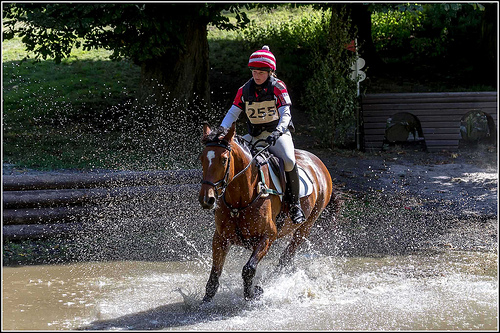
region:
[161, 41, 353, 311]
woman riding horse in competition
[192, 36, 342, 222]
rider wearing vest with three-digit number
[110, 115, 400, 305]
horse splashing through water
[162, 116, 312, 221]
rider holding onto reins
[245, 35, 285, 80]
rider wearing knitted red and white hat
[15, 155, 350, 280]
wooden barrier behind horse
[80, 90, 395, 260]
drops of water surrounding horse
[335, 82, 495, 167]
arched cutouts in wall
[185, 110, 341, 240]
rider wearing long black boots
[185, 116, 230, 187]
white splotch with tail between eyes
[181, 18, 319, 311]
Girl riding a horse.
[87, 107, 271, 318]
Horse in the water.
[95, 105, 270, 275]
Rider riding horse through the water.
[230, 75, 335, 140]
Rider with 255 on the jersey.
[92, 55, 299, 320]
Water spray from the horse running.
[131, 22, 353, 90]
Trees behind the horse rider.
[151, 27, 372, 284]
Girl riding in the water.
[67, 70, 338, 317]
Water polo.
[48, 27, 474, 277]
The horse is running through the water.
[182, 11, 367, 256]
Girl riding a horse with a jersey.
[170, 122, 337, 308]
A BROWN HORSE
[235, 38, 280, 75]
A RED AND WHITE HAT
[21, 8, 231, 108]
A TREE IN THE BACKGROUND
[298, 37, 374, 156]
TALL WEEDS BY THE FLAG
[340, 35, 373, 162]
A RED FLAG ON A POLE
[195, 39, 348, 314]
A PERSON RIDING A HORSE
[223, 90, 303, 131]
THE NUMBER 225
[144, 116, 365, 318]
A HORSE SPLASHING THROUGH THE WATER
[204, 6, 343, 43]
SUNSHINE IN THE DISTANCE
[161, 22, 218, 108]
A THICK TREE TRUNK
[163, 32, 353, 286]
person on horse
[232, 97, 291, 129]
bib with number 255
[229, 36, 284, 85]
water polo helmet that's striped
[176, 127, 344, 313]
brown horse that's racing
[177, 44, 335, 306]
girl racing on horse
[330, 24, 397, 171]
flag in corner of brick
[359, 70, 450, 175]
arch of bridge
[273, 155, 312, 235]
black leather riding boots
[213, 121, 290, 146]
black leather riding gloves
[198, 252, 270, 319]
horse with black feet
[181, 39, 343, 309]
female steeple chase racer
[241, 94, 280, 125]
number placard on steeple chase racer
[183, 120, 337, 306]
brown horse in steeple chase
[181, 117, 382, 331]
brown horse running in water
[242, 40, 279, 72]
red and white helmet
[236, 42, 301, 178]
woman riding on a horse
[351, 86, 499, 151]
wall jump for steeple chase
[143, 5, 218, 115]
tree trunk beside hurdle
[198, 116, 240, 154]
ears of a brown horse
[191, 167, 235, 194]
part of a horse bridle